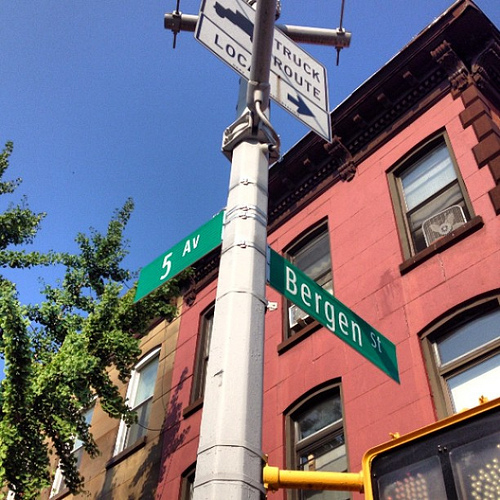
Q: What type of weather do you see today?
A: It is clear.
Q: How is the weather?
A: It is clear.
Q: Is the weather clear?
A: Yes, it is clear.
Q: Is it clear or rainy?
A: It is clear.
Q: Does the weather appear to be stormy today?
A: No, it is clear.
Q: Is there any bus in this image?
A: No, there are no buses.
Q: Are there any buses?
A: No, there are no buses.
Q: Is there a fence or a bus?
A: No, there are no buses or fences.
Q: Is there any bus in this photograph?
A: No, there are no buses.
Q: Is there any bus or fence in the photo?
A: No, there are no buses or fences.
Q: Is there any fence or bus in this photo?
A: No, there are no buses or fences.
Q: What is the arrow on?
A: The arrow is on the sign.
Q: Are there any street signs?
A: Yes, there is a street sign.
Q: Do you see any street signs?
A: Yes, there is a street sign.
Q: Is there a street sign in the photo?
A: Yes, there is a street sign.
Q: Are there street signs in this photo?
A: Yes, there is a street sign.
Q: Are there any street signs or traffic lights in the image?
A: Yes, there is a street sign.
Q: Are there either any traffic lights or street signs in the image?
A: Yes, there is a street sign.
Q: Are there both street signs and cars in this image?
A: No, there is a street sign but no cars.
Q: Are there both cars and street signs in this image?
A: No, there is a street sign but no cars.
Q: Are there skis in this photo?
A: No, there are no skis.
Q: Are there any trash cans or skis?
A: No, there are no skis or trash cans.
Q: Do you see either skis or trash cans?
A: No, there are no skis or trash cans.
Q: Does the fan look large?
A: Yes, the fan is large.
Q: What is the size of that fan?
A: The fan is large.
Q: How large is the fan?
A: The fan is large.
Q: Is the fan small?
A: No, the fan is large.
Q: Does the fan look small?
A: No, the fan is large.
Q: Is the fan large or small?
A: The fan is large.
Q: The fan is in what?
A: The fan is in the window.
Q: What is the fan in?
A: The fan is in the window.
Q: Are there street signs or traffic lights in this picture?
A: Yes, there is a street sign.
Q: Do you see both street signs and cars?
A: No, there is a street sign but no cars.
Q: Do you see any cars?
A: No, there are no cars.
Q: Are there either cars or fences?
A: No, there are no cars or fences.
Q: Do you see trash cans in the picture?
A: No, there are no trash cans.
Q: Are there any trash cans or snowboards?
A: No, there are no trash cans or snowboards.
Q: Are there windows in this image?
A: Yes, there is a window.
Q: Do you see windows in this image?
A: Yes, there is a window.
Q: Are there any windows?
A: Yes, there is a window.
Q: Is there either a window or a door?
A: Yes, there is a window.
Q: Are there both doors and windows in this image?
A: No, there is a window but no doors.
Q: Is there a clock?
A: No, there are no clocks.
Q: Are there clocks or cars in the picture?
A: No, there are no clocks or cars.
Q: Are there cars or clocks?
A: No, there are no clocks or cars.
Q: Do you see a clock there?
A: No, there are no clocks.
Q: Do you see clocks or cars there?
A: No, there are no clocks or cars.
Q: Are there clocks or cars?
A: No, there are no cars or clocks.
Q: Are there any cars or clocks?
A: No, there are no cars or clocks.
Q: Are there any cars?
A: No, there are no cars.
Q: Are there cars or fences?
A: No, there are no cars or fences.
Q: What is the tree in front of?
A: The tree is in front of the building.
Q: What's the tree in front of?
A: The tree is in front of the building.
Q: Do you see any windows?
A: Yes, there is a window.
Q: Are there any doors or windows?
A: Yes, there is a window.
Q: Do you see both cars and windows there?
A: No, there is a window but no cars.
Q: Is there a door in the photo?
A: No, there are no doors.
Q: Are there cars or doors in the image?
A: No, there are no doors or cars.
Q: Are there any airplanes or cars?
A: No, there are no cars or airplanes.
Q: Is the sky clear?
A: Yes, the sky is clear.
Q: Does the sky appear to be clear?
A: Yes, the sky is clear.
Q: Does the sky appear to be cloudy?
A: No, the sky is clear.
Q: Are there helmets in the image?
A: No, there are no helmets.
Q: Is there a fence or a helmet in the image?
A: No, there are no helmets or fences.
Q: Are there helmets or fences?
A: No, there are no helmets or fences.